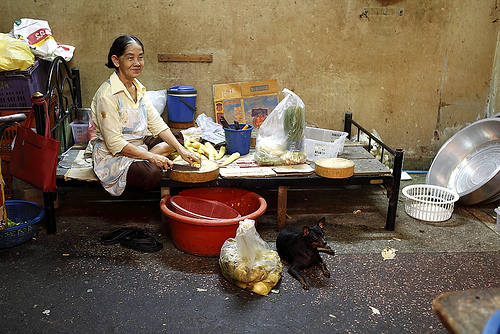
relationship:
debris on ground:
[380, 229, 405, 261] [3, 174, 499, 333]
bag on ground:
[218, 217, 284, 299] [3, 174, 499, 333]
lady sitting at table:
[88, 32, 205, 198] [47, 135, 393, 176]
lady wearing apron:
[88, 32, 205, 198] [93, 82, 151, 196]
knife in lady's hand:
[165, 159, 199, 172] [143, 148, 175, 171]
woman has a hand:
[88, 32, 205, 198] [143, 148, 175, 171]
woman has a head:
[88, 32, 205, 198] [101, 32, 146, 80]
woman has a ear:
[88, 32, 205, 198] [110, 52, 122, 70]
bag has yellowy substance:
[218, 217, 284, 299] [222, 249, 282, 294]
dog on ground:
[276, 211, 336, 290] [3, 174, 499, 333]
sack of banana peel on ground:
[218, 217, 284, 299] [3, 174, 499, 333]